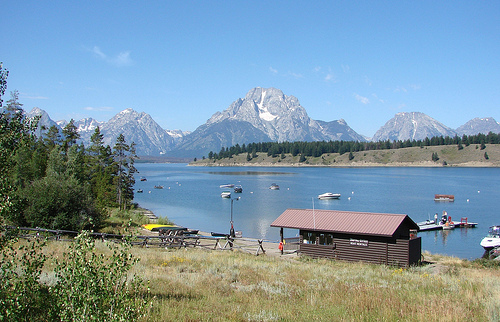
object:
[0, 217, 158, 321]
leaves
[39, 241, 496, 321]
grass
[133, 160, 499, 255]
water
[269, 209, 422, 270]
store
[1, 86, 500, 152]
mountains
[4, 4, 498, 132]
sky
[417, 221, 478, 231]
doc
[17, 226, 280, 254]
gate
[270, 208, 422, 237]
roof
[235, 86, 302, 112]
summit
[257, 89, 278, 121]
snow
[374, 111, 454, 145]
shape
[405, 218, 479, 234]
pier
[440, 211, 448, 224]
person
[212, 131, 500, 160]
forest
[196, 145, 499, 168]
land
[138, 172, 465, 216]
boats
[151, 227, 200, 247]
tables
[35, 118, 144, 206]
trees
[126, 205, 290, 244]
shoreline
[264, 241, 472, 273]
shore